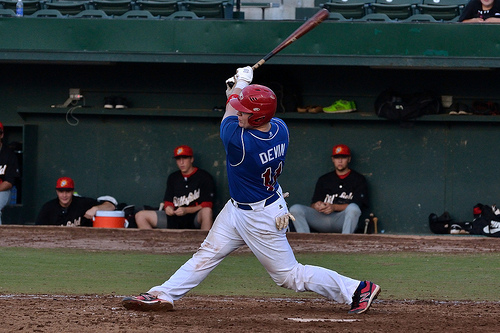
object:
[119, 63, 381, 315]
player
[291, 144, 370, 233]
man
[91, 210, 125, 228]
cooler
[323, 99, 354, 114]
sneaker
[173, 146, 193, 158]
cap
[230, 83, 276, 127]
helmet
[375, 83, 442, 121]
bag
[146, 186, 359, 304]
pants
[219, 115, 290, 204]
jersey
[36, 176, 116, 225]
guy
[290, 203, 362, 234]
pants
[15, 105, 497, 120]
shelf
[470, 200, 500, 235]
clothes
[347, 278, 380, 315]
shoe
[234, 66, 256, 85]
glove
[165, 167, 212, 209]
shirt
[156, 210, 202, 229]
shorts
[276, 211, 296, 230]
glove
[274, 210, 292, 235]
pocket